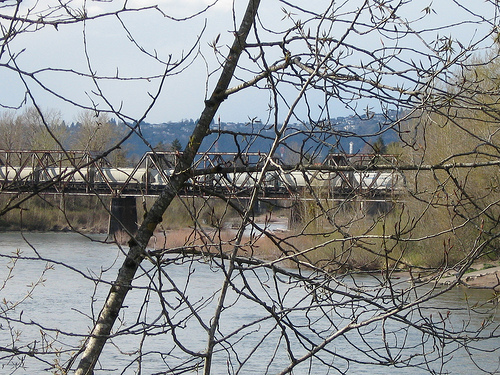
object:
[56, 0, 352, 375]
tree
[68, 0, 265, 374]
tree branch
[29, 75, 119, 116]
branches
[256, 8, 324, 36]
branches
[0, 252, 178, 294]
branch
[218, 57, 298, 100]
branch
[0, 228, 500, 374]
water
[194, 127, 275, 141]
branch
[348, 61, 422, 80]
branch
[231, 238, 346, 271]
branch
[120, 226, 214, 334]
branch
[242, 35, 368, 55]
branch